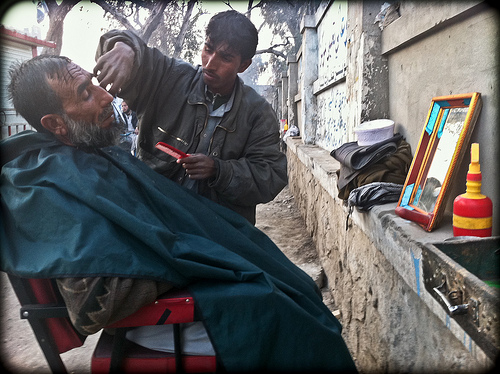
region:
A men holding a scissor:
[95, 14, 283, 159]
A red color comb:
[135, 135, 207, 185]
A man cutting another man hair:
[12, 10, 298, 197]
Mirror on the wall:
[380, 76, 478, 231]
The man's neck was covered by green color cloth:
[1, 46, 315, 323]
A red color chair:
[5, 263, 245, 366]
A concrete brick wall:
[285, 20, 435, 325]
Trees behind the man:
[76, 9, 336, 73]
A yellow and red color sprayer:
[432, 142, 490, 238]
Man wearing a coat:
[93, 15, 311, 201]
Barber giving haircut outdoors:
[89, 8, 269, 173]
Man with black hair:
[198, 8, 260, 90]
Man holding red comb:
[155, 7, 265, 167]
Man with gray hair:
[5, 48, 127, 152]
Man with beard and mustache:
[15, 48, 122, 153]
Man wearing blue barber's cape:
[1, 59, 147, 289]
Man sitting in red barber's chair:
[5, 50, 190, 370]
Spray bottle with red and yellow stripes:
[452, 139, 492, 236]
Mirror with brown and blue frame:
[394, 85, 477, 224]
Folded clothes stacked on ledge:
[335, 103, 405, 217]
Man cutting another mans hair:
[6, 8, 357, 373]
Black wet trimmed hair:
[6, 52, 71, 134]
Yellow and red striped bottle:
[450, 140, 494, 235]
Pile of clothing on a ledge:
[327, 115, 414, 230]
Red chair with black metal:
[3, 268, 223, 371]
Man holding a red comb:
[91, 8, 289, 230]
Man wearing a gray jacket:
[92, 8, 290, 226]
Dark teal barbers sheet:
[1, 125, 361, 372]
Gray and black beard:
[61, 113, 115, 151]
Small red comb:
[152, 139, 189, 160]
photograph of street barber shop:
[17, 11, 477, 351]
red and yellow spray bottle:
[445, 135, 491, 238]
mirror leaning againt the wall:
[399, 79, 481, 221]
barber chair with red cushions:
[29, 246, 251, 363]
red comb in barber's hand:
[138, 127, 200, 174]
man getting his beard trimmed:
[12, 17, 127, 146]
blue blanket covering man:
[20, 110, 363, 362]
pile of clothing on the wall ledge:
[330, 107, 405, 204]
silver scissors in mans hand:
[97, 40, 142, 132]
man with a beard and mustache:
[3, 41, 135, 159]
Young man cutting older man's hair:
[8, 8, 263, 155]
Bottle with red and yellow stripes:
[447, 143, 491, 238]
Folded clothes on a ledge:
[335, 118, 406, 208]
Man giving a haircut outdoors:
[100, 10, 262, 170]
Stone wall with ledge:
[297, 8, 331, 250]